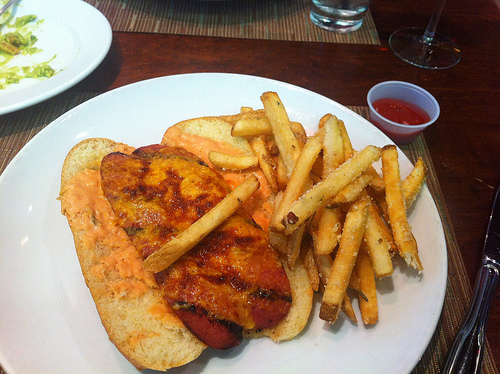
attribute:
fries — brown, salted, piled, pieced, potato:
[144, 91, 428, 327]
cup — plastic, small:
[367, 77, 440, 146]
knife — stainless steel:
[439, 181, 497, 373]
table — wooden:
[70, 1, 498, 373]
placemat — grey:
[80, 0, 381, 47]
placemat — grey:
[0, 89, 497, 373]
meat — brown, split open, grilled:
[97, 142, 291, 350]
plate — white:
[1, 71, 448, 373]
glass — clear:
[308, 0, 371, 34]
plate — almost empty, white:
[1, 1, 114, 116]